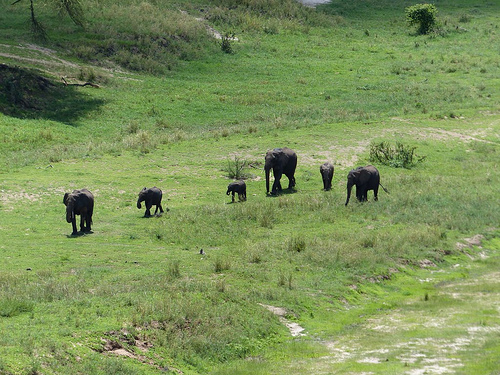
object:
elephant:
[40, 152, 389, 240]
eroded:
[95, 324, 180, 366]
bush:
[403, 0, 450, 38]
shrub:
[369, 140, 426, 169]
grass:
[1, 1, 499, 373]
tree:
[402, 4, 439, 36]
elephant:
[264, 146, 299, 195]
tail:
[379, 182, 391, 194]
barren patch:
[258, 298, 307, 338]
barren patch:
[321, 331, 494, 374]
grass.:
[0, 233, 498, 374]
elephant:
[62, 187, 95, 234]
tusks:
[67, 207, 77, 221]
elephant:
[226, 178, 247, 202]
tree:
[0, 55, 100, 111]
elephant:
[346, 164, 387, 201]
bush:
[223, 155, 247, 179]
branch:
[66, 1, 226, 81]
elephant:
[345, 165, 390, 207]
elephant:
[319, 163, 334, 190]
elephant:
[136, 187, 165, 218]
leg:
[373, 188, 379, 201]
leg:
[269, 174, 283, 196]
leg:
[154, 204, 159, 215]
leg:
[69, 211, 77, 234]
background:
[3, 1, 499, 107]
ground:
[1, 0, 498, 372]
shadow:
[1, 78, 72, 121]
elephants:
[61, 146, 390, 237]